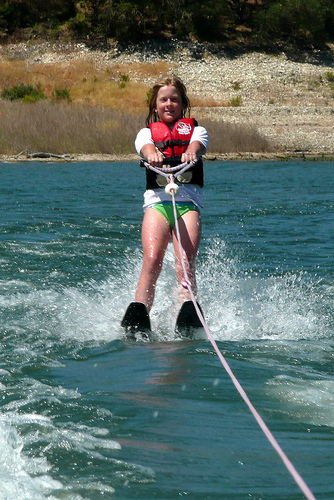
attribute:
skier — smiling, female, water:
[119, 75, 208, 335]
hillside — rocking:
[103, 50, 319, 91]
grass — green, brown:
[2, 53, 286, 160]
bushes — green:
[18, 70, 69, 114]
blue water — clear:
[26, 344, 333, 499]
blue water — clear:
[203, 158, 332, 272]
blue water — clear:
[1, 163, 145, 290]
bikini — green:
[156, 201, 197, 224]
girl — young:
[133, 75, 209, 306]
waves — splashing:
[61, 348, 311, 372]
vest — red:
[143, 115, 204, 188]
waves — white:
[30, 286, 112, 339]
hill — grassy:
[1, 22, 330, 158]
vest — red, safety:
[139, 116, 207, 189]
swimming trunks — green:
[149, 201, 200, 227]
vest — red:
[150, 122, 207, 188]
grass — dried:
[1, 57, 269, 155]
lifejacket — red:
[148, 113, 194, 159]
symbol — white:
[174, 118, 195, 136]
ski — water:
[118, 300, 154, 334]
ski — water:
[171, 302, 208, 340]